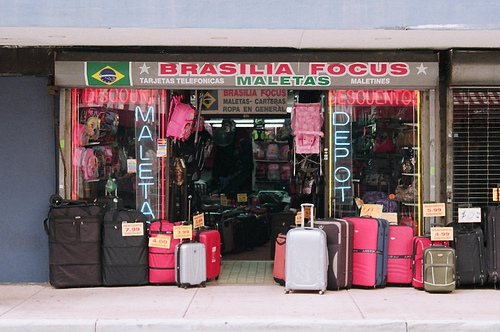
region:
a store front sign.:
[55, 43, 441, 108]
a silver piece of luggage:
[272, 197, 332, 302]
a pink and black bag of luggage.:
[341, 196, 404, 296]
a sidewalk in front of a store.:
[4, 286, 498, 303]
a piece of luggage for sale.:
[286, 94, 337, 160]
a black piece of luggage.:
[44, 185, 111, 290]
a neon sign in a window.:
[112, 99, 169, 234]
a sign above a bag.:
[419, 221, 458, 247]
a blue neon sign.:
[329, 96, 360, 208]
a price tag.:
[93, 209, 158, 253]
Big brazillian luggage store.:
[21, 46, 497, 305]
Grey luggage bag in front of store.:
[283, 195, 328, 298]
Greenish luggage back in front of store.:
[423, 231, 459, 298]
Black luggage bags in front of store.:
[461, 202, 498, 292]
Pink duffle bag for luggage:
[145, 216, 179, 289]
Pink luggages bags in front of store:
[353, 213, 415, 300]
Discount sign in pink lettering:
[77, 86, 164, 104]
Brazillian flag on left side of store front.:
[81, 61, 136, 92]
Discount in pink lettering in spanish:
[330, 91, 420, 105]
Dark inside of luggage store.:
[191, 124, 286, 223]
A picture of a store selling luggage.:
[35, 38, 480, 308]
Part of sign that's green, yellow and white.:
[81, 55, 140, 88]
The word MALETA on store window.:
[128, 100, 170, 226]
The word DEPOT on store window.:
[326, 108, 358, 207]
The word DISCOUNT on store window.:
[77, 80, 162, 105]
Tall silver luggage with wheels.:
[275, 190, 332, 300]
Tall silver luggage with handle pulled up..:
[281, 197, 331, 297]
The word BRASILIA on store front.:
[155, 58, 295, 78]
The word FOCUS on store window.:
[301, 57, 413, 77]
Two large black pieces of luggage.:
[43, 183, 151, 295]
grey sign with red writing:
[85, 57, 432, 107]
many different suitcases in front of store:
[10, 172, 498, 310]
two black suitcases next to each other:
[27, 180, 154, 282]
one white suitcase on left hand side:
[165, 237, 222, 298]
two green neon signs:
[118, 102, 376, 210]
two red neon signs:
[65, 71, 440, 114]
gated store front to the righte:
[444, 51, 498, 229]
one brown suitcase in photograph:
[417, 232, 471, 302]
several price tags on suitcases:
[88, 187, 476, 252]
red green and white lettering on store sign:
[31, 45, 458, 105]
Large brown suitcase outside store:
[40, 198, 106, 296]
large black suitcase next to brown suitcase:
[38, 199, 156, 285]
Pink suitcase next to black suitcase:
[105, 209, 190, 290]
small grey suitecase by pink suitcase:
[166, 234, 218, 291]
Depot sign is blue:
[332, 111, 355, 211]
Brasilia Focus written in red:
[157, 61, 407, 92]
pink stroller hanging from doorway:
[285, 95, 338, 180]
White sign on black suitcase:
[446, 201, 487, 301]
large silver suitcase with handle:
[279, 198, 338, 301]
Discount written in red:
[83, 88, 162, 117]